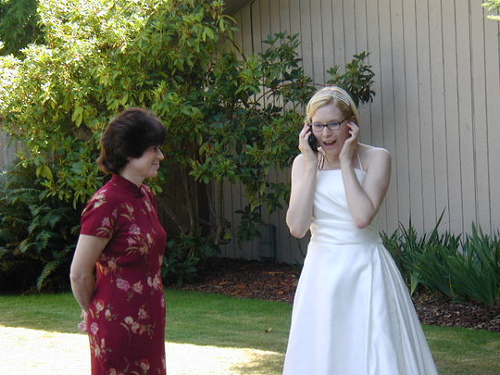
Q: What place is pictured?
A: It is a yard.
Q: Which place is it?
A: It is a yard.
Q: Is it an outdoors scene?
A: Yes, it is outdoors.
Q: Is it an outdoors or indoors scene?
A: It is outdoors.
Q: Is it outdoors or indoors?
A: It is outdoors.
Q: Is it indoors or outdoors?
A: It is outdoors.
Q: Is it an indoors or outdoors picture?
A: It is outdoors.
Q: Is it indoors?
A: No, it is outdoors.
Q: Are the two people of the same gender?
A: Yes, all the people are female.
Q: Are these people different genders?
A: No, all the people are female.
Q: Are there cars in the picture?
A: No, there are no cars.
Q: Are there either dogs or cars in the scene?
A: No, there are no cars or dogs.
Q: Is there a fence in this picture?
A: Yes, there is a fence.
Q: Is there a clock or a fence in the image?
A: Yes, there is a fence.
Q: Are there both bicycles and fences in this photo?
A: No, there is a fence but no bikes.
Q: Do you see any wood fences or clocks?
A: Yes, there is a wood fence.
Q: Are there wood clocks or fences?
A: Yes, there is a wood fence.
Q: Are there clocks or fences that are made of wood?
A: Yes, the fence is made of wood.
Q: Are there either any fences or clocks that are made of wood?
A: Yes, the fence is made of wood.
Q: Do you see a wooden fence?
A: Yes, there is a wood fence.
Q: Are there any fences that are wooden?
A: Yes, there is a fence that is wooden.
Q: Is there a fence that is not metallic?
A: Yes, there is a wooden fence.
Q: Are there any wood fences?
A: Yes, there is a fence that is made of wood.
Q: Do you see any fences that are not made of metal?
A: Yes, there is a fence that is made of wood.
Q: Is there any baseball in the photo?
A: No, there are no baseballs.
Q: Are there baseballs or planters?
A: No, there are no baseballs or planters.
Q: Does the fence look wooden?
A: Yes, the fence is wooden.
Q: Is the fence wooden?
A: Yes, the fence is wooden.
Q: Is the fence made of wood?
A: Yes, the fence is made of wood.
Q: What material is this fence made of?
A: The fence is made of wood.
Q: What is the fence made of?
A: The fence is made of wood.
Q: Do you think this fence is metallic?
A: No, the fence is wooden.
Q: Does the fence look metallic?
A: No, the fence is wooden.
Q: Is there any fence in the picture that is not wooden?
A: No, there is a fence but it is wooden.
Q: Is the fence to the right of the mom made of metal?
A: No, the fence is made of wood.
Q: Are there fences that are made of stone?
A: No, there is a fence but it is made of wood.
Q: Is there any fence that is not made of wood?
A: No, there is a fence but it is made of wood.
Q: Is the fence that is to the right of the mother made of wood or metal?
A: The fence is made of wood.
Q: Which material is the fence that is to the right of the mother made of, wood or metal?
A: The fence is made of wood.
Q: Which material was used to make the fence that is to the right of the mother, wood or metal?
A: The fence is made of wood.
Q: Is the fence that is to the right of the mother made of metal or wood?
A: The fence is made of wood.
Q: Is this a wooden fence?
A: Yes, this is a wooden fence.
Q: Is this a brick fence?
A: No, this is a wooden fence.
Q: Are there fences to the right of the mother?
A: Yes, there is a fence to the right of the mother.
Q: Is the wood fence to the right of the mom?
A: Yes, the fence is to the right of the mom.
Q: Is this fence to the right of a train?
A: No, the fence is to the right of the mom.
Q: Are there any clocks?
A: No, there are no clocks.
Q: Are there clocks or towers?
A: No, there are no clocks or towers.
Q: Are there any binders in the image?
A: No, there are no binders.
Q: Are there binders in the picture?
A: No, there are no binders.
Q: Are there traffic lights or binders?
A: No, there are no binders or traffic lights.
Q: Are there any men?
A: No, there are no men.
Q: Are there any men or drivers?
A: No, there are no men or drivers.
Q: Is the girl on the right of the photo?
A: Yes, the girl is on the right of the image.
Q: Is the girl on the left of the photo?
A: No, the girl is on the right of the image.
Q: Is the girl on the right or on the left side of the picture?
A: The girl is on the right of the image.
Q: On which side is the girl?
A: The girl is on the right of the image.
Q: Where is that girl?
A: The girl is in the yard.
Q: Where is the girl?
A: The girl is in the yard.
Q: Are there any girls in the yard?
A: Yes, there is a girl in the yard.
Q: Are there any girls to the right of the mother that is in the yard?
A: Yes, there is a girl to the right of the mother.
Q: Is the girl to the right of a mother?
A: Yes, the girl is to the right of a mother.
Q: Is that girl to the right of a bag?
A: No, the girl is to the right of a mother.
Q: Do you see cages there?
A: No, there are no cages.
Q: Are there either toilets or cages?
A: No, there are no cages or toilets.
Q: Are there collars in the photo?
A: Yes, there is a collar.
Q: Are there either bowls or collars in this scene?
A: Yes, there is a collar.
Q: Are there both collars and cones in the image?
A: No, there is a collar but no cones.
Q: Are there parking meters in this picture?
A: No, there are no parking meters.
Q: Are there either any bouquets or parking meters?
A: No, there are no parking meters or bouquets.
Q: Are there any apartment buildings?
A: No, there are no apartment buildings.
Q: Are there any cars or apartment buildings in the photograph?
A: No, there are no apartment buildings or cars.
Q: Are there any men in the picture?
A: No, there are no men.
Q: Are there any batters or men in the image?
A: No, there are no men or batters.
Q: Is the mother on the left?
A: Yes, the mother is on the left of the image.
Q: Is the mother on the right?
A: No, the mother is on the left of the image.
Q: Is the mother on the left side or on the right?
A: The mother is on the left of the image.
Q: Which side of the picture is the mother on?
A: The mother is on the left of the image.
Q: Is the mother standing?
A: Yes, the mother is standing.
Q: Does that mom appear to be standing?
A: Yes, the mom is standing.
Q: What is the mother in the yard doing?
A: The mother is standing.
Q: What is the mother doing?
A: The mother is standing.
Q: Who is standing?
A: The mother is standing.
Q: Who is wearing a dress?
A: The mom is wearing a dress.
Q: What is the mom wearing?
A: The mom is wearing a dress.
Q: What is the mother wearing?
A: The mom is wearing a dress.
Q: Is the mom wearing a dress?
A: Yes, the mom is wearing a dress.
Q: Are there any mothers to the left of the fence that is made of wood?
A: Yes, there is a mother to the left of the fence.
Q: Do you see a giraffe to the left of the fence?
A: No, there is a mother to the left of the fence.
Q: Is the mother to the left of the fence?
A: Yes, the mother is to the left of the fence.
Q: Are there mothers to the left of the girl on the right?
A: Yes, there is a mother to the left of the girl.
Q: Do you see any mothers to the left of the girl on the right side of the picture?
A: Yes, there is a mother to the left of the girl.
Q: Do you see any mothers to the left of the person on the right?
A: Yes, there is a mother to the left of the girl.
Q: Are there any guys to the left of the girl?
A: No, there is a mother to the left of the girl.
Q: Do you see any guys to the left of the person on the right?
A: No, there is a mother to the left of the girl.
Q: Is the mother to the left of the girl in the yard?
A: Yes, the mother is to the left of the girl.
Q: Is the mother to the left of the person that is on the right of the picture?
A: Yes, the mother is to the left of the girl.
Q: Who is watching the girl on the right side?
A: The mom is watching the girl.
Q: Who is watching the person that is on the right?
A: The mom is watching the girl.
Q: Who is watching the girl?
A: The mom is watching the girl.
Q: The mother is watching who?
A: The mother is watching the girl.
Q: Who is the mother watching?
A: The mother is watching the girl.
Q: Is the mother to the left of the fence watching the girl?
A: Yes, the mother is watching the girl.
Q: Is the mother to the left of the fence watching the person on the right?
A: Yes, the mother is watching the girl.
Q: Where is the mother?
A: The mother is in the yard.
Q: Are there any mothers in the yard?
A: Yes, there is a mother in the yard.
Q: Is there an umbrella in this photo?
A: No, there are no umbrellas.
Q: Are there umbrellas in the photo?
A: No, there are no umbrellas.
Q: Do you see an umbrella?
A: No, there are no umbrellas.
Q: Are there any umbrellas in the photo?
A: No, there are no umbrellas.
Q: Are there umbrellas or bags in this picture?
A: No, there are no umbrellas or bags.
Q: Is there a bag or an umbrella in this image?
A: No, there are no umbrellas or bags.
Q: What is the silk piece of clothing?
A: The clothing item is a dress.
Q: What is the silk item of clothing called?
A: The clothing item is a dress.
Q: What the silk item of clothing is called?
A: The clothing item is a dress.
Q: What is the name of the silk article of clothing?
A: The clothing item is a dress.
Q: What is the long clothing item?
A: The clothing item is a dress.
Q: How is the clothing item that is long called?
A: The clothing item is a dress.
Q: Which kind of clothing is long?
A: The clothing is a dress.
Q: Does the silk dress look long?
A: Yes, the dress is long.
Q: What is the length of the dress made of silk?
A: The dress is long.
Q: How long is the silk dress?
A: The dress is long.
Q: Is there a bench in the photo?
A: No, there are no benches.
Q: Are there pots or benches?
A: No, there are no benches or pots.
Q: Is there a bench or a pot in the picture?
A: No, there are no benches or pots.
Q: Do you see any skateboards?
A: No, there are no skateboards.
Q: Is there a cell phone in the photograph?
A: Yes, there is a cell phone.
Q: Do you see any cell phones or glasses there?
A: Yes, there is a cell phone.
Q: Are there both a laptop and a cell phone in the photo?
A: No, there is a cell phone but no laptops.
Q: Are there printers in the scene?
A: No, there are no printers.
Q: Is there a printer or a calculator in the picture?
A: No, there are no printers or calculators.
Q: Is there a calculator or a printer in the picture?
A: No, there are no printers or calculators.